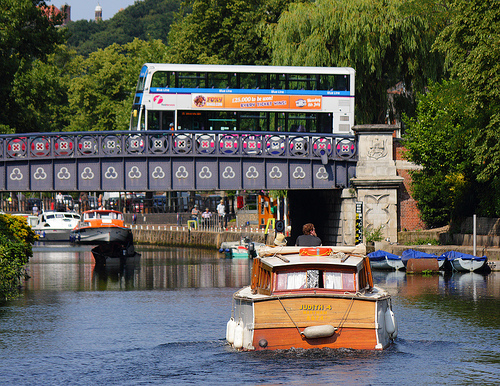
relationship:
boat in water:
[217, 238, 398, 353] [1, 251, 497, 385]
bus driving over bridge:
[126, 56, 356, 142] [3, 126, 355, 197]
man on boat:
[292, 217, 324, 250] [217, 238, 398, 353]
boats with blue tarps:
[369, 252, 485, 274] [372, 248, 483, 265]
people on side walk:
[190, 195, 229, 228] [119, 225, 271, 243]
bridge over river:
[3, 126, 355, 197] [1, 251, 497, 385]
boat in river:
[217, 238, 398, 353] [1, 251, 497, 385]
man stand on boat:
[292, 217, 324, 250] [217, 238, 398, 353]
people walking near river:
[190, 195, 229, 228] [1, 251, 497, 385]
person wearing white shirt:
[214, 197, 230, 231] [215, 203, 227, 218]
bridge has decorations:
[3, 126, 355, 197] [7, 164, 329, 184]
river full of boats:
[1, 251, 497, 385] [1, 209, 491, 352]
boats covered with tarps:
[369, 252, 485, 274] [372, 248, 483, 265]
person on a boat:
[292, 217, 324, 250] [217, 238, 398, 353]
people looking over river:
[190, 195, 229, 228] [1, 251, 497, 385]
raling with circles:
[3, 126, 355, 197] [3, 133, 359, 160]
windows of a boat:
[275, 266, 354, 286] [217, 238, 398, 353]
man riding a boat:
[292, 217, 324, 250] [217, 238, 398, 353]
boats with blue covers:
[369, 252, 485, 274] [372, 248, 483, 265]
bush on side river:
[1, 209, 40, 305] [1, 251, 497, 385]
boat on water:
[217, 238, 398, 353] [1, 251, 497, 385]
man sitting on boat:
[292, 217, 324, 250] [217, 238, 398, 353]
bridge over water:
[3, 126, 355, 197] [1, 251, 497, 385]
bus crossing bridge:
[126, 56, 356, 142] [3, 126, 355, 197]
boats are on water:
[369, 252, 485, 274] [1, 251, 497, 385]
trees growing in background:
[5, 2, 499, 125] [1, 2, 498, 66]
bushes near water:
[1, 209, 40, 305] [1, 251, 497, 385]